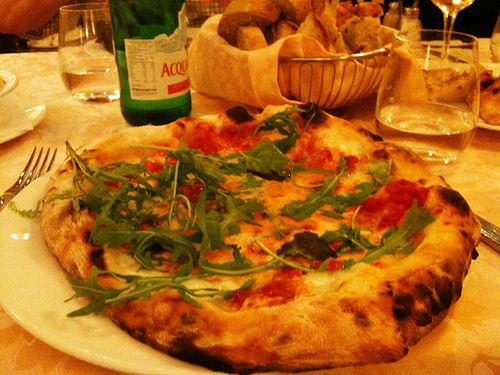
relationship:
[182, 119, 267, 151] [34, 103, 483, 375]
red sauce on food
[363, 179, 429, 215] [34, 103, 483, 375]
red sauce on food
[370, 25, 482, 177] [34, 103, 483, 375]
glass next to food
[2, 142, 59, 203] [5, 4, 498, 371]
fork on table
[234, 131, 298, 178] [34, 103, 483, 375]
lettuce on food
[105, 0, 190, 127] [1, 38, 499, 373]
bottle on table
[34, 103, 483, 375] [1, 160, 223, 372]
food on plate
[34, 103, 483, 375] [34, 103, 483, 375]
food on food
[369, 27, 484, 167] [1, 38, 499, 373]
cup on table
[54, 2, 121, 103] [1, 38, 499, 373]
cup on table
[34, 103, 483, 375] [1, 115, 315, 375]
food on dinner plate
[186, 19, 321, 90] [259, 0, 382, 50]
cloth under bread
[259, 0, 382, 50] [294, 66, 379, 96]
bread in bowl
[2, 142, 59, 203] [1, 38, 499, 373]
fork on a table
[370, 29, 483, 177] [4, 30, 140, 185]
glass on a table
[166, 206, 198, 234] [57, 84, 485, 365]
basil on a pizza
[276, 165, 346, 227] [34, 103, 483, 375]
basil on a food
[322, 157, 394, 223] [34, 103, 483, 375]
basil on a food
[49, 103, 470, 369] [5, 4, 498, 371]
food sitting on table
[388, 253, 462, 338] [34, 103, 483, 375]
spot on food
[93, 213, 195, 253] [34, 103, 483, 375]
lettuce on food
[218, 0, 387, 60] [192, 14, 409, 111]
bread in basket